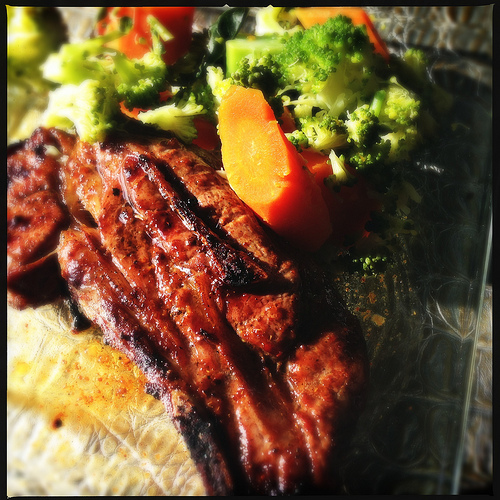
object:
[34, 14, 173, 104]
broccoli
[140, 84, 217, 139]
broccoli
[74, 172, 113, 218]
color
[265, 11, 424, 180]
broccoli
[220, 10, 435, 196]
vegetable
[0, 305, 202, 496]
surface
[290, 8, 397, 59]
carrots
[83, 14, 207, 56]
carrots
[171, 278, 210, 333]
sauce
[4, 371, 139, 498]
bread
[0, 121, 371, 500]
chicken breast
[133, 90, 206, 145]
broccoli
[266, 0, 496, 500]
plate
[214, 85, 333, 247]
carrot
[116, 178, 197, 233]
chicken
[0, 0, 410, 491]
meal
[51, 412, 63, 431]
stain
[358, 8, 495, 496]
background